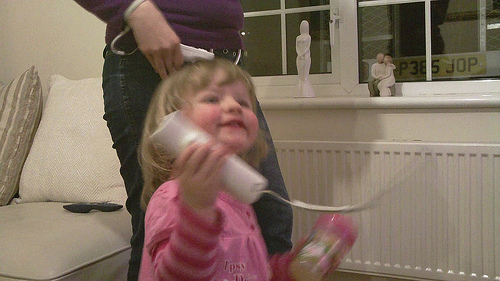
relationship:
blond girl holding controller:
[133, 59, 341, 281] [150, 109, 263, 206]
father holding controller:
[70, 0, 295, 281] [151, 98, 293, 219]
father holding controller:
[70, 0, 295, 281] [141, 20, 238, 72]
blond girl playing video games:
[133, 59, 341, 281] [151, 112, 460, 218]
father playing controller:
[70, 0, 295, 281] [178, 43, 216, 61]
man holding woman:
[366, 49, 384, 99] [381, 53, 400, 99]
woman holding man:
[381, 53, 400, 99] [366, 49, 384, 99]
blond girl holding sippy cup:
[133, 59, 341, 281] [288, 198, 360, 279]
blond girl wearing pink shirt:
[133, 59, 341, 281] [136, 177, 293, 281]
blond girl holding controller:
[133, 59, 341, 281] [150, 110, 268, 204]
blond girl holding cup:
[133, 59, 341, 281] [278, 182, 380, 279]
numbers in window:
[398, 55, 480, 77] [354, 3, 498, 83]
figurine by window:
[294, 19, 316, 98] [241, 0, 498, 98]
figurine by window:
[369, 52, 399, 97] [241, 0, 498, 98]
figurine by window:
[294, 19, 312, 98] [241, 0, 498, 98]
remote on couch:
[63, 202, 124, 213] [2, 198, 132, 276]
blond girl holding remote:
[133, 59, 341, 281] [140, 107, 265, 205]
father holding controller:
[70, 0, 292, 280] [178, 43, 216, 61]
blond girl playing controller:
[133, 59, 341, 281] [150, 110, 268, 204]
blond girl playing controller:
[133, 59, 341, 281] [178, 43, 216, 61]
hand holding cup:
[282, 233, 309, 275] [291, 201, 358, 279]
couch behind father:
[5, 68, 103, 279] [70, 0, 295, 281]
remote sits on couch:
[63, 196, 125, 218] [0, 64, 129, 281]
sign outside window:
[398, 52, 498, 76] [358, 4, 498, 71]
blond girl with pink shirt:
[141, 58, 264, 186] [136, 177, 268, 273]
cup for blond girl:
[283, 213, 360, 281] [133, 59, 341, 281]